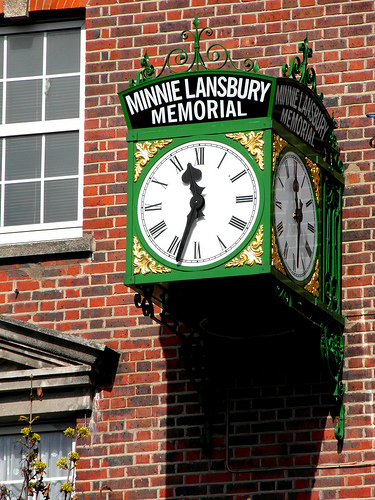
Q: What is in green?
A: Clock.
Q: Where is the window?
A: On building.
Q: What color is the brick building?
A: Red.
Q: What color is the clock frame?
A: Green.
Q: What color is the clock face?
A: White.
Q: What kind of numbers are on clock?
A: Roman numerals.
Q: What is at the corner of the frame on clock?
A: Decorative design.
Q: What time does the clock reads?
A: 11:33.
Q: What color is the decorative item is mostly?
A: Green.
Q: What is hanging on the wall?
A: A clock.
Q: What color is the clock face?
A: White.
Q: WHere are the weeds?
A: On the corner.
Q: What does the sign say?
A: Minnie Lansbury Memorial.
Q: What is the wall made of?
A: Red brick.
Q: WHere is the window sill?
A: Under the window.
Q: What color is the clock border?
A: Green.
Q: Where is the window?
A: On the building.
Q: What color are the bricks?
A: Red.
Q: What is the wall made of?
A: Brick.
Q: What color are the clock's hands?
A: Black.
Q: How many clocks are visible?
A: Two.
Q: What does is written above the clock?
A: Minnie Lansbury Memorial.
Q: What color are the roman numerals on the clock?
A: Black.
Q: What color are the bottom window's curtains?
A: White.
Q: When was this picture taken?
A: During the daytime.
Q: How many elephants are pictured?
A: Zero.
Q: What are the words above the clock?
A: Minnie Lansbury Memorial.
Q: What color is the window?
A: White.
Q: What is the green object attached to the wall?
A: A clock.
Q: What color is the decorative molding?
A: Gray.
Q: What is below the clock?
A: A shadow.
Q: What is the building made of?
A: Brick.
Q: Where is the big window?
A: To the left of the clock.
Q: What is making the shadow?
A: The clock.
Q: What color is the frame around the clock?
A: Green.